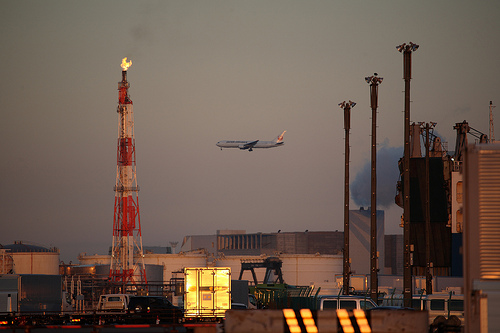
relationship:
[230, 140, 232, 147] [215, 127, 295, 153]
window on plane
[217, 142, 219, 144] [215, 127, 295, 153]
window on plane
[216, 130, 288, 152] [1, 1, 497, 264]
plane in sky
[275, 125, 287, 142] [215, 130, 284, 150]
tail on plane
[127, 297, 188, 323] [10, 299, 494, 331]
car on ground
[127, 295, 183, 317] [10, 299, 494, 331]
car on ground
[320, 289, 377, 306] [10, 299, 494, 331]
car on ground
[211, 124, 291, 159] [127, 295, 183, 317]
plane above car